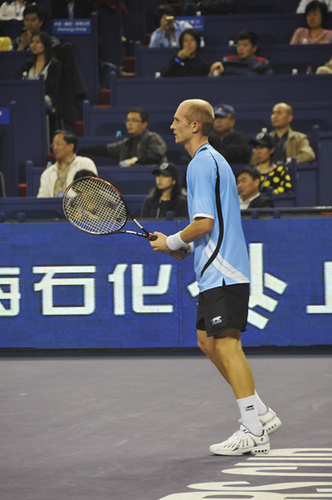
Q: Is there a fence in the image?
A: No, there are no fences.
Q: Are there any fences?
A: No, there are no fences.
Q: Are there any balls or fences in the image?
A: No, there are no fences or balls.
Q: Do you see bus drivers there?
A: No, there are no bus drivers.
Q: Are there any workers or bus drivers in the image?
A: No, there are no bus drivers or workers.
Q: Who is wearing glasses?
A: The man is wearing glasses.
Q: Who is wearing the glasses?
A: The man is wearing glasses.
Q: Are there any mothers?
A: No, there are no mothers.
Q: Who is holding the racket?
A: The man is holding the racket.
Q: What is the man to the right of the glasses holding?
A: The man is holding the tennis racket.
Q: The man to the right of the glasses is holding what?
A: The man is holding the tennis racket.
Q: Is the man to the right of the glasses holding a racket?
A: Yes, the man is holding a racket.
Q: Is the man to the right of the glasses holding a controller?
A: No, the man is holding a racket.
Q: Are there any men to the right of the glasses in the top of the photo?
A: Yes, there is a man to the right of the glasses.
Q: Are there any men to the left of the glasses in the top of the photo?
A: No, the man is to the right of the glasses.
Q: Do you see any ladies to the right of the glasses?
A: No, there is a man to the right of the glasses.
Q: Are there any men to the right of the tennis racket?
A: Yes, there is a man to the right of the tennis racket.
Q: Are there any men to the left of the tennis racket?
A: No, the man is to the right of the tennis racket.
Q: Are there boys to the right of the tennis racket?
A: No, there is a man to the right of the tennis racket.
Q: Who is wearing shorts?
A: The man is wearing shorts.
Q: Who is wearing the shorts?
A: The man is wearing shorts.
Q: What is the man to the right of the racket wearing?
A: The man is wearing shorts.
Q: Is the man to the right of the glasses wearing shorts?
A: Yes, the man is wearing shorts.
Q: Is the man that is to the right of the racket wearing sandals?
A: No, the man is wearing shorts.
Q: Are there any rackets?
A: Yes, there is a racket.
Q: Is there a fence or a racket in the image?
A: Yes, there is a racket.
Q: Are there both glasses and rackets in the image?
A: Yes, there are both a racket and glasses.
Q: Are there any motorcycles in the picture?
A: No, there are no motorcycles.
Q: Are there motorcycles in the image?
A: No, there are no motorcycles.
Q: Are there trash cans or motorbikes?
A: No, there are no motorbikes or trash cans.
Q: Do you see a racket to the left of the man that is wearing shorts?
A: Yes, there is a racket to the left of the man.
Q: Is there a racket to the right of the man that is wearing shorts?
A: No, the racket is to the left of the man.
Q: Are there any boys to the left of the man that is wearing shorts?
A: No, there is a racket to the left of the man.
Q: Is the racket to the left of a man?
A: Yes, the racket is to the left of a man.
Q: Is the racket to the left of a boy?
A: No, the racket is to the left of a man.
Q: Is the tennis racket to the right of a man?
A: No, the tennis racket is to the left of a man.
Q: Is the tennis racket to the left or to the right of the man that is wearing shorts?
A: The tennis racket is to the left of the man.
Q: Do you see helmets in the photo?
A: No, there are no helmets.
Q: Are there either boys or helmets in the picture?
A: No, there are no helmets or boys.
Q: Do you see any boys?
A: No, there are no boys.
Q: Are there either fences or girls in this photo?
A: No, there are no fences or girls.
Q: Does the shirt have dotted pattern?
A: Yes, the shirt is dotted.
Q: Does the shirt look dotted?
A: Yes, the shirt is dotted.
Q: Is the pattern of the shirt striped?
A: No, the shirt is dotted.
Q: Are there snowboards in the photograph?
A: No, there are no snowboards.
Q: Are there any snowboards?
A: No, there are no snowboards.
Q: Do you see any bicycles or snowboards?
A: No, there are no snowboards or bicycles.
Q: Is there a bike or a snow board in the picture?
A: No, there are no snowboards or bikes.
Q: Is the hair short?
A: Yes, the hair is short.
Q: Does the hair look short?
A: Yes, the hair is short.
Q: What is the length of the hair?
A: The hair is short.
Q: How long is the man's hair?
A: The hair is short.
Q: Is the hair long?
A: No, the hair is short.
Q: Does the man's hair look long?
A: No, the hair is short.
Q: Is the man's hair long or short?
A: The hair is short.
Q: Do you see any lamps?
A: No, there are no lamps.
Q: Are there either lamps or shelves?
A: No, there are no lamps or shelves.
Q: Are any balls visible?
A: No, there are no balls.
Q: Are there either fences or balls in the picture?
A: No, there are no balls or fences.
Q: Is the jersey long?
A: Yes, the jersey is long.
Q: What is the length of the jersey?
A: The jersey is long.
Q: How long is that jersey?
A: The jersey is long.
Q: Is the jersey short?
A: No, the jersey is long.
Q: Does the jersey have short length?
A: No, the jersey is long.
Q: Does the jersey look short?
A: No, the jersey is long.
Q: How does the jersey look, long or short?
A: The jersey is long.